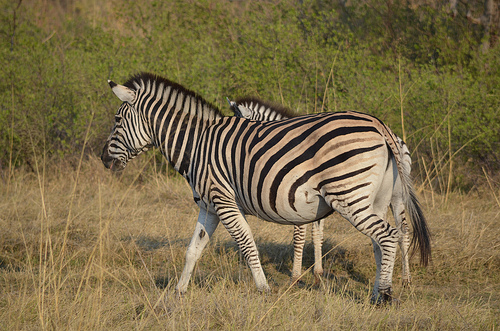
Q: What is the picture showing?
A: It is showing a field.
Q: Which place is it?
A: It is a field.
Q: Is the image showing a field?
A: Yes, it is showing a field.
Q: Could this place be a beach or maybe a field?
A: It is a field.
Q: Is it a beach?
A: No, it is a field.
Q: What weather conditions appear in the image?
A: It is sunny.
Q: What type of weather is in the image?
A: It is sunny.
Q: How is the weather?
A: It is sunny.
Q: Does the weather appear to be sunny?
A: Yes, it is sunny.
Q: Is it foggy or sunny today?
A: It is sunny.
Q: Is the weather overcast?
A: No, it is sunny.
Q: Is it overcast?
A: No, it is sunny.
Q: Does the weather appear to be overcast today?
A: No, it is sunny.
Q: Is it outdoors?
A: Yes, it is outdoors.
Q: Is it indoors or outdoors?
A: It is outdoors.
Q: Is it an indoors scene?
A: No, it is outdoors.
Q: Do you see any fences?
A: No, there are no fences.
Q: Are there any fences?
A: No, there are no fences.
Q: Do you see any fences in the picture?
A: No, there are no fences.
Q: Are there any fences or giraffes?
A: No, there are no fences or giraffes.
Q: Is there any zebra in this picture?
A: Yes, there is a zebra.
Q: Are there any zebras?
A: Yes, there is a zebra.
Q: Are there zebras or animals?
A: Yes, there is a zebra.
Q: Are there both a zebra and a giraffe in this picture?
A: No, there is a zebra but no giraffes.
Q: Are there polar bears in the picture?
A: No, there are no polar bears.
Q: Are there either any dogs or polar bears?
A: No, there are no polar bears or dogs.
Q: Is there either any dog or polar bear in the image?
A: No, there are no polar bears or dogs.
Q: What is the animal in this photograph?
A: The animal is a zebra.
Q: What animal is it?
A: The animal is a zebra.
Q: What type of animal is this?
A: This is a zebra.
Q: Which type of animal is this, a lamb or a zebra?
A: This is a zebra.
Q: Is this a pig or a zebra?
A: This is a zebra.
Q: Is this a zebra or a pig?
A: This is a zebra.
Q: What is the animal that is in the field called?
A: The animal is a zebra.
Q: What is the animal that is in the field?
A: The animal is a zebra.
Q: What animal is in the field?
A: The animal is a zebra.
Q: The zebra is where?
A: The zebra is in the field.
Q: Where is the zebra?
A: The zebra is in the field.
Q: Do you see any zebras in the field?
A: Yes, there is a zebra in the field.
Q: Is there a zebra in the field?
A: Yes, there is a zebra in the field.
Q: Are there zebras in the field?
A: Yes, there is a zebra in the field.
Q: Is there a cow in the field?
A: No, there is a zebra in the field.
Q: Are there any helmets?
A: No, there are no helmets.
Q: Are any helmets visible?
A: No, there are no helmets.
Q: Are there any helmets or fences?
A: No, there are no helmets or fences.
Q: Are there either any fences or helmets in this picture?
A: No, there are no helmets or fences.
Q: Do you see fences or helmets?
A: No, there are no helmets or fences.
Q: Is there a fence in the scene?
A: No, there are no fences.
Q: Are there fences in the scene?
A: No, there are no fences.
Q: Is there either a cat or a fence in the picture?
A: No, there are no fences or cats.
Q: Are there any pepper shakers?
A: No, there are no pepper shakers.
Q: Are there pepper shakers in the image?
A: No, there are no pepper shakers.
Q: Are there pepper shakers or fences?
A: No, there are no pepper shakers or fences.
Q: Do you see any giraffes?
A: No, there are no giraffes.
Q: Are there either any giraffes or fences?
A: No, there are no giraffes or fences.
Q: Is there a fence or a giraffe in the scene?
A: No, there are no giraffes or fences.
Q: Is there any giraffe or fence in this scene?
A: No, there are no giraffes or fences.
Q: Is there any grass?
A: Yes, there is grass.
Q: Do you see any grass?
A: Yes, there is grass.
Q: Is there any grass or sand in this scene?
A: Yes, there is grass.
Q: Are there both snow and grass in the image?
A: No, there is grass but no snow.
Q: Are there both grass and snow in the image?
A: No, there is grass but no snow.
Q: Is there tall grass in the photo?
A: Yes, there is tall grass.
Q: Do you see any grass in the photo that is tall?
A: Yes, there is grass that is tall.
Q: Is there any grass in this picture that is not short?
A: Yes, there is tall grass.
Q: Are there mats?
A: No, there are no mats.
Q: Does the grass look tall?
A: Yes, the grass is tall.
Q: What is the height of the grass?
A: The grass is tall.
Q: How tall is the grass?
A: The grass is tall.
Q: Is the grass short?
A: No, the grass is tall.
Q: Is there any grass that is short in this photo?
A: No, there is grass but it is tall.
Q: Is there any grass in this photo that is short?
A: No, there is grass but it is tall.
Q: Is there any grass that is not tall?
A: No, there is grass but it is tall.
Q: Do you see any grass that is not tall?
A: No, there is grass but it is tall.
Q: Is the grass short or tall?
A: The grass is tall.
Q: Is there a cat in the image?
A: No, there are no cats.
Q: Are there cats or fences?
A: No, there are no cats or fences.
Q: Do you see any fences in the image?
A: No, there are no fences.